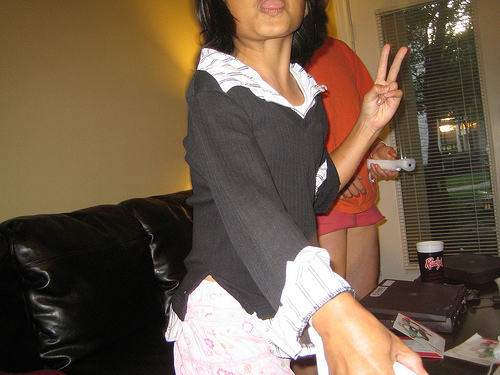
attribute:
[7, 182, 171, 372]
couch — black, leather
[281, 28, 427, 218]
top — long, orange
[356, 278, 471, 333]
briefcase — closed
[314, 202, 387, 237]
pants — pink, short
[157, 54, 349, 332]
sweater — dark grey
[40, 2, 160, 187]
wall — beige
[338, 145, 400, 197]
hands — raised